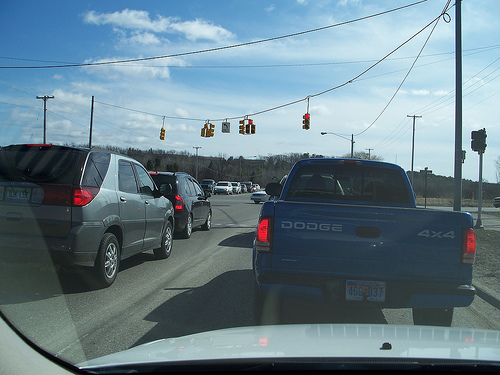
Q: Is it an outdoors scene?
A: Yes, it is outdoors.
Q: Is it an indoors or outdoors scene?
A: It is outdoors.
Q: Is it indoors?
A: No, it is outdoors.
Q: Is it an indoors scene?
A: No, it is outdoors.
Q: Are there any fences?
A: No, there are no fences.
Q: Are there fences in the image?
A: No, there are no fences.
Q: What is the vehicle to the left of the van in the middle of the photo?
A: The vehicle is a car.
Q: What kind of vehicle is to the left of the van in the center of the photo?
A: The vehicle is a car.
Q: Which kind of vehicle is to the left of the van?
A: The vehicle is a car.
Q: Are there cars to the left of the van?
A: Yes, there is a car to the left of the van.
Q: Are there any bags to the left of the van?
A: No, there is a car to the left of the van.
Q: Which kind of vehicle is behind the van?
A: The vehicle is a car.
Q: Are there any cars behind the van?
A: Yes, there is a car behind the van.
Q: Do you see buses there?
A: No, there are no buses.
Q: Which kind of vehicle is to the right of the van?
A: The vehicle is a car.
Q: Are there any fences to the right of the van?
A: No, there is a car to the right of the van.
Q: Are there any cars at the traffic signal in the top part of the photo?
A: Yes, there is a car at the traffic light.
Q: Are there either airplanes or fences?
A: No, there are no fences or airplanes.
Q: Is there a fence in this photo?
A: No, there are no fences.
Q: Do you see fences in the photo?
A: No, there are no fences.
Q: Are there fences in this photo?
A: No, there are no fences.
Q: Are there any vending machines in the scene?
A: No, there are no vending machines.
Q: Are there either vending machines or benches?
A: No, there are no vending machines or benches.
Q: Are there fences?
A: No, there are no fences.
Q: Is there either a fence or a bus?
A: No, there are no fences or buses.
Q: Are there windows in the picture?
A: Yes, there are windows.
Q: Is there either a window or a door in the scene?
A: Yes, there are windows.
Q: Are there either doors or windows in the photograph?
A: Yes, there are windows.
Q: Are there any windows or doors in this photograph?
A: Yes, there are windows.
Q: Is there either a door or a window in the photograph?
A: Yes, there are windows.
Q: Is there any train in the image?
A: No, there are no trains.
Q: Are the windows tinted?
A: Yes, the windows are tinted.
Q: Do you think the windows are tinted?
A: Yes, the windows are tinted.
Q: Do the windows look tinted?
A: Yes, the windows are tinted.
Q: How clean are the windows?
A: The windows are tinted.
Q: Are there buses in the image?
A: No, there are no buses.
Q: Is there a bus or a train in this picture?
A: No, there are no buses or trains.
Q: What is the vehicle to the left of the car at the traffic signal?
A: The vehicle is a van.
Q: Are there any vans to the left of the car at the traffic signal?
A: Yes, there is a van to the left of the car.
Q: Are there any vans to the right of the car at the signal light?
A: No, the van is to the left of the car.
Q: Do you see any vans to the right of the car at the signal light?
A: No, the van is to the left of the car.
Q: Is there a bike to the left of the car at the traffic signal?
A: No, there is a van to the left of the car.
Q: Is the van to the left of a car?
A: Yes, the van is to the left of a car.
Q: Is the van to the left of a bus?
A: No, the van is to the left of a car.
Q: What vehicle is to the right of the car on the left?
A: The vehicle is a van.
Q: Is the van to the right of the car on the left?
A: Yes, the van is to the right of the car.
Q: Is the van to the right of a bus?
A: No, the van is to the right of the car.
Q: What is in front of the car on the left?
A: The van is in front of the car.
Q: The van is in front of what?
A: The van is in front of the car.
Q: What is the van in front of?
A: The van is in front of the car.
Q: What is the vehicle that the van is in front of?
A: The vehicle is a car.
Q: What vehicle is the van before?
A: The van is in front of the car.